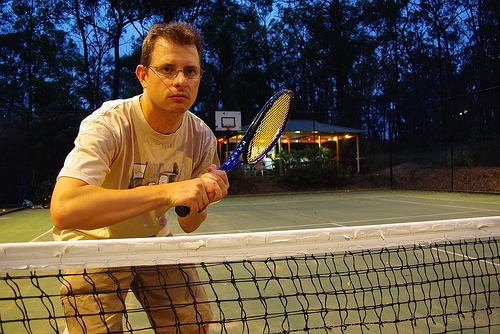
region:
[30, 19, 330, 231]
Man is playing tennis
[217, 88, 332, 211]
Man holding a blue tennis racket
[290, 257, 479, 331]
net is black and white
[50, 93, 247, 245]
Man wearing a short sleeve tshirt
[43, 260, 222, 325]
man wearing khaki shorts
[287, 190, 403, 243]
The court has white paint on it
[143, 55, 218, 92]
Man is wearing glasses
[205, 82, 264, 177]
basketball goal in the background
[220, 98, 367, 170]
Tent with lights on the ceiling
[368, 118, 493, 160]
Fence around the court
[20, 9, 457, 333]
this man is ready to play tennis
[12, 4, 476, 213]
he is playing tennis at night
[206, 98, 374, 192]
this is some kind of lighted building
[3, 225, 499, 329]
this is a tennis net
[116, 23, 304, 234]
he is ready to return a hit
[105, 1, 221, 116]
this man has an intense look on his face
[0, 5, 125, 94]
the night sky behind the trees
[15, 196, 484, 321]
light is shining on the tennis court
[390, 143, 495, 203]
mud covered ground near the court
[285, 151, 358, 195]
bushes near the building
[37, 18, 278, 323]
man playing tennis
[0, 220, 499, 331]
tennis net with white top and black netting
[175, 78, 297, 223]
yellow and blue tennis racket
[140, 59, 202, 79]
eye glasses of tennis player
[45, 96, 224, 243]
white short sleeve shirt of tennis player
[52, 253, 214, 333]
beige pants of tennis player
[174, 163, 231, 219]
hands holding tennis racket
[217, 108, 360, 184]
shelter in the background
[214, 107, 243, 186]
basketball hoop in the background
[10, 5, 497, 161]
trees behind tennis player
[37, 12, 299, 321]
man standing behind tennis net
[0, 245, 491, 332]
black mesh of tennis net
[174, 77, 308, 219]
blue racket with yellow webbing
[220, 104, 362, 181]
shelter with lights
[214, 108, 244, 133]
basketball hoop backboard with red box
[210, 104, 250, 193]
basketball hoop in background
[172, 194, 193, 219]
black handle of tennis racket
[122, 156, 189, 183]
design on front of sweatshirt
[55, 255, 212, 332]
beige pants of man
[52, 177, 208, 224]
foream of tennis player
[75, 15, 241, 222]
A man playing tennis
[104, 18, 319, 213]
A man playing tennis in the evening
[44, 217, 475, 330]
A net acrosses tennis court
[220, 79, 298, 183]
Tennis racket is black and blue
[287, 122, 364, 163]
Lights under a shelter are on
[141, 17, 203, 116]
Man has brown hair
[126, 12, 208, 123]
Man is wearing glasses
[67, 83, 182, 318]
Man wearing tan shirt and khaki shorts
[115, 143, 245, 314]
man wearing khaki shorts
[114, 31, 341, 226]
Man holding tennis racket